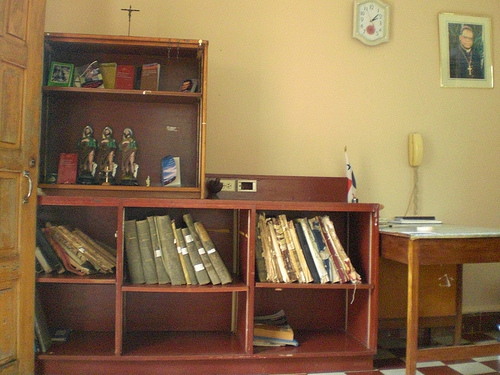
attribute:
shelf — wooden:
[39, 32, 209, 199]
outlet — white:
[218, 177, 237, 189]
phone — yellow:
[406, 130, 425, 166]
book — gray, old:
[124, 218, 145, 285]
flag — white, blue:
[344, 143, 358, 201]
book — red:
[114, 64, 137, 92]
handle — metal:
[22, 169, 35, 205]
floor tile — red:
[417, 363, 466, 373]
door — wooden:
[2, 0, 48, 374]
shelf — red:
[35, 175, 384, 374]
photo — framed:
[446, 21, 485, 79]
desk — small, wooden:
[377, 218, 499, 373]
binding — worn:
[259, 210, 282, 284]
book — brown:
[148, 215, 172, 283]